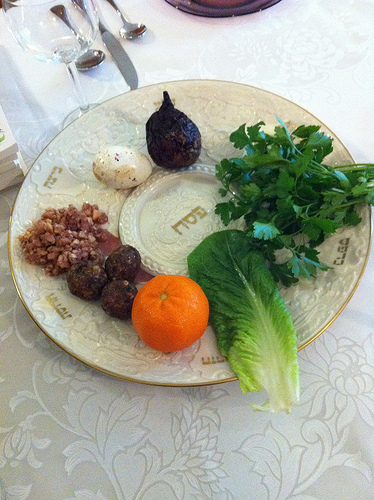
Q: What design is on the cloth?
A: Flowers.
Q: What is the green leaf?
A: Romaine.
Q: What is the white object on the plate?
A: Egg.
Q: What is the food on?
A: Plate.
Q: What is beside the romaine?
A: Cilantro.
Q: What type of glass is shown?
A: Wine.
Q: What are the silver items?
A: Utensils.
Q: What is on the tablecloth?
A: Floral design.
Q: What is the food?
A: Jewish.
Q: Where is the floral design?
A: On the cloth.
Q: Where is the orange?
A: On the plate.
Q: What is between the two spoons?
A: A knife.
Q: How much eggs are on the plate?
A: One.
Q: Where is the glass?
A: Next to the plate.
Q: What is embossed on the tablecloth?
A: A floral design.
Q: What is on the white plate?
A: Food.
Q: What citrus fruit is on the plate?
A: An orange.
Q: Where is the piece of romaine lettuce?
A: On the plate.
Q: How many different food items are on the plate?
A: Seven.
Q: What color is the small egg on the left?
A: White.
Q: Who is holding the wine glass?
A: No one.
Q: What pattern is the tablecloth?
A: Flowers.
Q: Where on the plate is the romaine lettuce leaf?
A: Bottom right.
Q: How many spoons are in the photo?
A: Two.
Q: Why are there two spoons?
A: Tea and soup spoons.